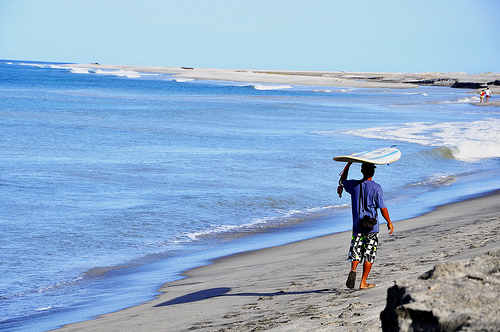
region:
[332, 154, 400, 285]
this is a man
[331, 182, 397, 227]
man wearing a blue shirt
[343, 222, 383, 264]
man wearing plaid shorts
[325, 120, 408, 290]
man carrying on surfboard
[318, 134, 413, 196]
surfboard on mans head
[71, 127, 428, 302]
man walking on shore line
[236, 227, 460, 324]
this is a beach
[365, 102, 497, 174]
white foam on water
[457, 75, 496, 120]
people standing in water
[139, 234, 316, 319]
shadow of man on beach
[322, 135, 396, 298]
Man walking along the beach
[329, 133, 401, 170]
Surfboard on man's head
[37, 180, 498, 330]
Sand covering the beach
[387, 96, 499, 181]
White wave crashing on the shore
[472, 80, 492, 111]
Couple walking in the water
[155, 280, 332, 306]
Shadow on the ground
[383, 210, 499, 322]
Large rock on the beach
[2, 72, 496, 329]
Water is blue and calm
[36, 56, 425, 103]
Waves crashing all over the beach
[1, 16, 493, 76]
Sky is completely free of clouds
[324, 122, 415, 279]
surfer carrying board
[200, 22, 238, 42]
white clouds in blue sky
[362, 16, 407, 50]
white clouds in blue sky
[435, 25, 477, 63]
white clouds in blue sky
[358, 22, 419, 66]
white clouds in blue sky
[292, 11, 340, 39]
white clouds in blue sky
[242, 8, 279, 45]
white clouds in blue sky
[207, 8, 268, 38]
white clouds in blue sky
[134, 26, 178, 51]
white clouds in blue sky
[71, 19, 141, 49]
white clouds in blue sky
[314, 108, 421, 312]
the person is carrying a surfboard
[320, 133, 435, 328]
he is holding it up with one arm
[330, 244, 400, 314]
he is wearing flip flops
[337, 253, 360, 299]
the bottom sole of his flip flop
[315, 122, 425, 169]
the surfboard is atop his head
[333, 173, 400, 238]
his shirt is blue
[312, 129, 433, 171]
the board is white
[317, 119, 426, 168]
the board has blue stripes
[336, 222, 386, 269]
his boardshorts are patterned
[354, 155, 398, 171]
he is wearing a baseball cap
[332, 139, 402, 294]
man walking with surfboard on his head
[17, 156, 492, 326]
man walking across the beach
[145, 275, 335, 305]
man's shadow on the ground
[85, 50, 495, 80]
another beach on the opposite side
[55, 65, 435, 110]
wave coming to shore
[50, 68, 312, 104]
waves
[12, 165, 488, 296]
tide going in and out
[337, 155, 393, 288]
man is wearing a blue shirt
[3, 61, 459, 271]
ocean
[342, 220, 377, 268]
man wearing black and white long shorts